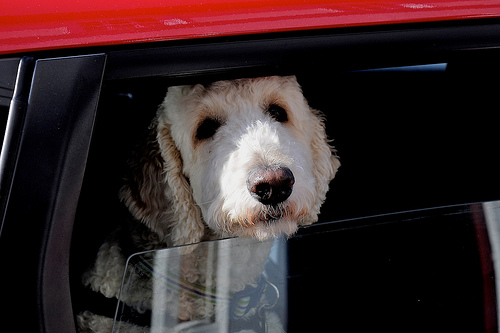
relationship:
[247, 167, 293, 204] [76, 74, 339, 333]
nose of dog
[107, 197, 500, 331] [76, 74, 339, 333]
window near dog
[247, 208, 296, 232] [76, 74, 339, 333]
mouth of dog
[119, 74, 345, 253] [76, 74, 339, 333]
head of dog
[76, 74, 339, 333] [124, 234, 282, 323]
dog wearing collar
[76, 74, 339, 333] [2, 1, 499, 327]
dog sitting in car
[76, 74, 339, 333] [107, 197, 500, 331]
dog near window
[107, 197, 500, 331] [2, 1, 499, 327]
window of car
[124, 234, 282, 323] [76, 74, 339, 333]
collar of dog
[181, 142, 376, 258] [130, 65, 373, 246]
snout of dog